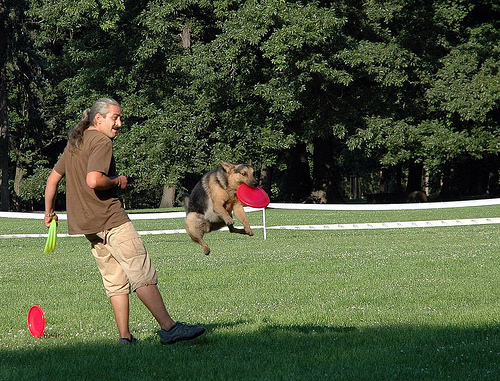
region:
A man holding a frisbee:
[28, 72, 203, 362]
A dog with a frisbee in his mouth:
[180, 131, 275, 270]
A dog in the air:
[173, 134, 300, 316]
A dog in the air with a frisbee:
[167, 133, 292, 263]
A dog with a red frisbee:
[165, 129, 283, 270]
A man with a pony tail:
[42, 83, 135, 158]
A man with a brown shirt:
[30, 78, 220, 375]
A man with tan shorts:
[72, 215, 172, 300]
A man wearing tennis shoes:
[95, 314, 229, 361]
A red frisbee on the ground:
[15, 295, 55, 350]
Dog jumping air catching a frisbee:
[182, 155, 267, 255]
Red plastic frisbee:
[235, 180, 267, 206]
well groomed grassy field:
[0, 206, 499, 376]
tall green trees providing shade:
[0, 0, 495, 195]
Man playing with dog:
[40, 95, 200, 345]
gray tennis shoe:
[155, 316, 205, 341]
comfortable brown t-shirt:
[45, 125, 125, 230]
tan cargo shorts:
[81, 220, 156, 295]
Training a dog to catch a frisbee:
[45, 95, 270, 346]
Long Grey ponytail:
[65, 105, 90, 146]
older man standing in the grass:
[22, 58, 203, 353]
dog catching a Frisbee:
[172, 126, 291, 263]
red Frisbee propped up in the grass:
[19, 299, 47, 339]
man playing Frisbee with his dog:
[25, 74, 332, 357]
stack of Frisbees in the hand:
[37, 217, 62, 256]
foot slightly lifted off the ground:
[147, 322, 214, 346]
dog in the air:
[175, 137, 283, 256]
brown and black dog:
[162, 149, 279, 261]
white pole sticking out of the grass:
[255, 207, 275, 242]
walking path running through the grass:
[2, 211, 499, 246]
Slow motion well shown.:
[35, 83, 287, 301]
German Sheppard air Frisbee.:
[182, 155, 282, 254]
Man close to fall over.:
[73, 85, 196, 364]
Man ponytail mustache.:
[59, 91, 142, 156]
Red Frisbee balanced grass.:
[12, 288, 57, 351]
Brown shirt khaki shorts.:
[70, 130, 163, 295]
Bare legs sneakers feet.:
[85, 290, 217, 351]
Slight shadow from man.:
[172, 303, 272, 340]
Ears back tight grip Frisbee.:
[207, 148, 277, 207]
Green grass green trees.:
[272, 8, 495, 336]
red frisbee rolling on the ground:
[25, 304, 44, 339]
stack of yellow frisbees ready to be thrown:
[42, 216, 59, 257]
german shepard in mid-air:
[182, 157, 258, 257]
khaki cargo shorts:
[84, 219, 159, 301]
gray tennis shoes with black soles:
[112, 318, 205, 348]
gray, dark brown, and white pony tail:
[65, 103, 92, 154]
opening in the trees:
[342, 172, 367, 202]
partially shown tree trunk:
[178, 27, 191, 50]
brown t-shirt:
[51, 126, 134, 237]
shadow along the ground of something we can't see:
[0, 318, 498, 379]